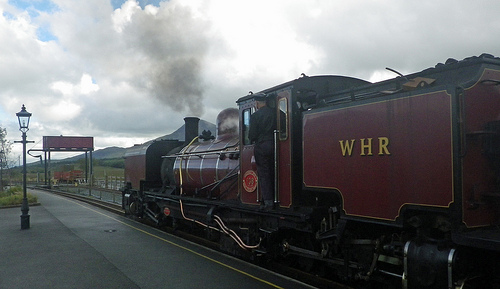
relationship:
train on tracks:
[126, 102, 493, 223] [51, 184, 115, 208]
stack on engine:
[183, 114, 201, 143] [172, 143, 239, 198]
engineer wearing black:
[247, 94, 274, 206] [246, 111, 282, 187]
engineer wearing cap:
[247, 94, 274, 206] [250, 92, 271, 104]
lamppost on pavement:
[9, 105, 37, 234] [9, 229, 94, 267]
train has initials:
[126, 102, 493, 223] [339, 134, 390, 159]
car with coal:
[305, 99, 488, 246] [432, 53, 494, 86]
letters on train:
[331, 129, 400, 169] [126, 102, 493, 223]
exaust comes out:
[126, 13, 215, 119] [182, 111, 199, 120]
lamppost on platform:
[9, 105, 37, 234] [3, 209, 234, 288]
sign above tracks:
[34, 127, 98, 158] [51, 184, 115, 208]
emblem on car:
[239, 170, 260, 196] [235, 76, 315, 231]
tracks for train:
[51, 184, 115, 208] [126, 102, 493, 223]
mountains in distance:
[18, 119, 215, 174] [7, 135, 237, 152]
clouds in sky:
[67, 14, 453, 55] [24, 5, 57, 42]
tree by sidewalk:
[2, 130, 15, 194] [18, 189, 83, 213]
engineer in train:
[247, 94, 274, 206] [126, 102, 493, 223]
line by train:
[19, 186, 278, 288] [126, 102, 493, 223]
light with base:
[12, 105, 34, 136] [18, 202, 36, 235]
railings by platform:
[75, 190, 121, 202] [3, 209, 234, 288]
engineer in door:
[247, 94, 274, 206] [236, 102, 291, 205]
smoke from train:
[149, 13, 205, 98] [126, 102, 493, 223]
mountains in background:
[18, 119, 215, 174] [7, 135, 237, 152]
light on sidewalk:
[14, 105, 30, 136] [18, 189, 83, 213]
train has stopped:
[126, 102, 493, 223] [119, 191, 190, 231]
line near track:
[142, 231, 187, 254] [77, 186, 113, 215]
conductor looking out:
[245, 107, 285, 189] [182, 111, 199, 120]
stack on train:
[183, 114, 201, 143] [126, 102, 493, 223]